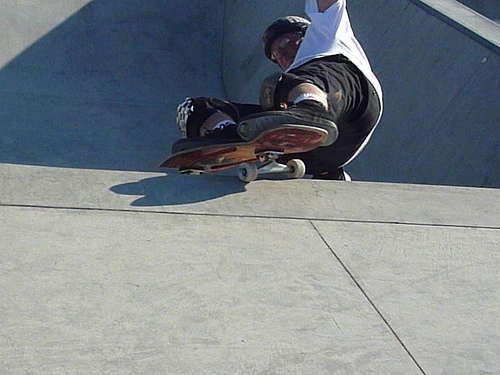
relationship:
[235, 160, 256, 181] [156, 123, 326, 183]
wheel on left of board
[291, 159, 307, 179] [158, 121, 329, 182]
wheel on skate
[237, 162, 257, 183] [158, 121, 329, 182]
wheel on skate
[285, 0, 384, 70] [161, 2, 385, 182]
shirt on boy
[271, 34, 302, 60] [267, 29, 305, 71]
eyeglasses on face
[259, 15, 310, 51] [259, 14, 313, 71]
helmet on head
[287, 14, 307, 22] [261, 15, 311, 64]
lettering on side of helmet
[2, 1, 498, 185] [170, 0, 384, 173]
wall in back of boy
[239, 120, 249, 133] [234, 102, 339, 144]
hole in bottom of shoe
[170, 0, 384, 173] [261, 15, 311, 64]
boy wearing helmet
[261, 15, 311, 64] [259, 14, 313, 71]
helmet on head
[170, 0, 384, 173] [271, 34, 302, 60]
boy wearing eyeglasses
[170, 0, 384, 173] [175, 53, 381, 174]
boy wearing pants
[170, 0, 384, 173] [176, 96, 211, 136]
boy wearing knee pad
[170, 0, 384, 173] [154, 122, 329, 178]
boy standing on skateboard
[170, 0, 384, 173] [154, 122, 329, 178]
boy on a skateboard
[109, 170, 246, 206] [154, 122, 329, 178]
shadow of a skateboard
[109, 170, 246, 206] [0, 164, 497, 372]
shadow on ground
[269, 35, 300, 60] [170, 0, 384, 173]
eyeglasses on a boy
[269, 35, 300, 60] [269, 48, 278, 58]
eyeglasses on a eye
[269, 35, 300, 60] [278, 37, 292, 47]
eyeglasses on a eye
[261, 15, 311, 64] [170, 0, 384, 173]
helmet on boy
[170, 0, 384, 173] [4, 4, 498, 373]
boy at skate park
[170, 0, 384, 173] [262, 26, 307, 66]
boy wearing glasses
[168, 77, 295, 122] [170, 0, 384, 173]
knee pads on boy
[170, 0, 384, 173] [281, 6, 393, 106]
boy wearing shirt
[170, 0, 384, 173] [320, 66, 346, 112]
boy wearing pants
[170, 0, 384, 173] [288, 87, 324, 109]
boy wearing socks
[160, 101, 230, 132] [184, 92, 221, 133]
kneepad on knee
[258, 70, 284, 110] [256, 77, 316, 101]
knee pads on knee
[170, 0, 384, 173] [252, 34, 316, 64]
boy wearing glasses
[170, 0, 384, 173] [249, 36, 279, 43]
boy wearing helmet